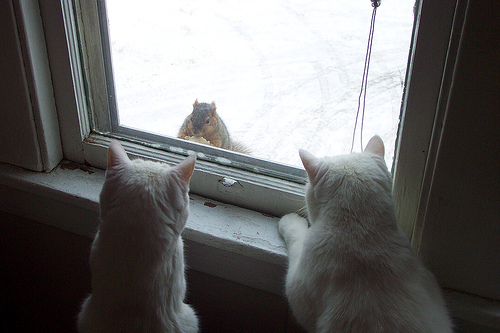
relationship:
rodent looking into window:
[174, 90, 225, 150] [67, 1, 385, 181]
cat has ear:
[279, 134, 454, 331] [296, 146, 333, 178]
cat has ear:
[279, 134, 454, 331] [365, 132, 385, 159]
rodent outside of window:
[177, 98, 250, 155] [106, 0, 417, 178]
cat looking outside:
[277, 134, 454, 331] [108, 3, 433, 191]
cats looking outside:
[84, 135, 198, 288] [108, 3, 433, 191]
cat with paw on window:
[279, 134, 454, 331] [49, 1, 434, 232]